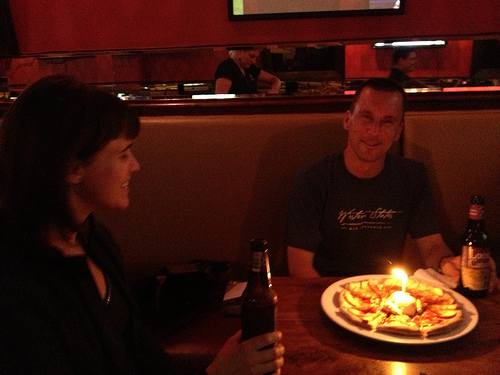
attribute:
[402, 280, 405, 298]
candle — lit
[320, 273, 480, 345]
plate — white, circular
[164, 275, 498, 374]
table — wood, wooden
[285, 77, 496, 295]
person — looking, smiling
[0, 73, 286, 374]
person — smiling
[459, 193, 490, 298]
beer — bottle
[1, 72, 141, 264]
hair — dark, brown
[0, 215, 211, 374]
shirt — black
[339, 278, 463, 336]
pizza — birthday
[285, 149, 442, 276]
tee shirt — black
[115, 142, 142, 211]
face — smiling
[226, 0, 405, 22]
mirror — long, horizontal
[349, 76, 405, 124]
hair — very short, brown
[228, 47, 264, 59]
hair — blonde